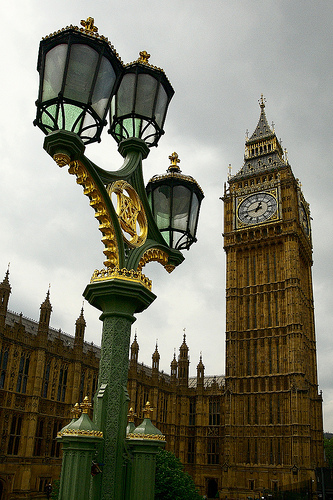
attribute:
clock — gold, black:
[234, 186, 283, 229]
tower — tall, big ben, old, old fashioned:
[220, 91, 327, 499]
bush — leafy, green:
[153, 450, 200, 500]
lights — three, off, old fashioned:
[34, 16, 203, 257]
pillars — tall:
[0, 267, 210, 500]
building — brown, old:
[0, 95, 322, 499]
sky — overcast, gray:
[1, 2, 332, 436]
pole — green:
[57, 278, 169, 500]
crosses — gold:
[67, 395, 158, 423]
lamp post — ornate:
[34, 14, 203, 500]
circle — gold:
[106, 179, 148, 249]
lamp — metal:
[32, 16, 123, 168]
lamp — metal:
[106, 47, 173, 150]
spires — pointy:
[1, 265, 208, 389]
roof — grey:
[3, 309, 228, 391]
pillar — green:
[83, 281, 158, 499]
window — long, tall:
[7, 350, 31, 463]